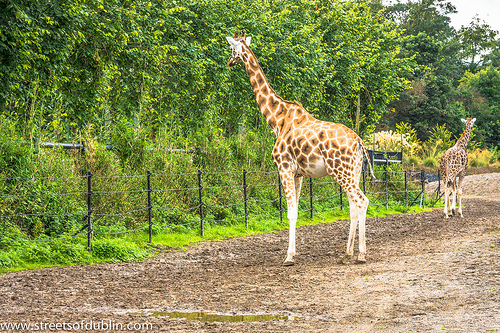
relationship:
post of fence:
[82, 171, 96, 249] [41, 116, 474, 279]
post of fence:
[191, 173, 212, 238] [30, 95, 335, 257]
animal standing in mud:
[225, 31, 376, 266] [1, 171, 498, 331]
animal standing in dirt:
[436, 115, 476, 221] [386, 215, 493, 321]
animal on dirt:
[225, 31, 376, 266] [386, 215, 493, 321]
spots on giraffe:
[291, 140, 355, 180] [184, 21, 371, 267]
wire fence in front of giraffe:
[4, 157, 441, 266] [432, 112, 479, 220]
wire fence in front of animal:
[4, 157, 441, 266] [225, 31, 376, 266]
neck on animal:
[239, 53, 278, 125] [225, 31, 376, 266]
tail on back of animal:
[356, 129, 377, 182] [225, 31, 376, 266]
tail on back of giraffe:
[441, 152, 451, 188] [432, 112, 479, 220]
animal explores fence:
[433, 115, 476, 221] [0, 169, 440, 254]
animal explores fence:
[220, 31, 380, 265] [0, 169, 440, 254]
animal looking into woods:
[225, 31, 376, 266] [20, 13, 209, 138]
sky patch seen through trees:
[448, 26, 498, 69] [437, 28, 497, 120]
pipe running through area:
[27, 140, 402, 166] [0, 0, 490, 327]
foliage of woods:
[18, 16, 193, 153] [0, 0, 498, 270]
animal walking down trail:
[436, 115, 476, 221] [6, 173, 496, 330]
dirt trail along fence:
[0, 200, 492, 331] [0, 136, 271, 260]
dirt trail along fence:
[0, 200, 492, 331] [373, 168, 443, 205]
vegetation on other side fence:
[1, 118, 420, 258] [2, 171, 442, 248]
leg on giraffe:
[355, 197, 375, 258] [222, 38, 390, 263]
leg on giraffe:
[341, 195, 363, 252] [222, 38, 390, 263]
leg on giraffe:
[283, 197, 302, 265] [222, 38, 390, 263]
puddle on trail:
[126, 298, 298, 330] [6, 173, 496, 330]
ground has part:
[395, 272, 451, 308] [401, 259, 438, 303]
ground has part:
[395, 272, 451, 308] [384, 272, 409, 311]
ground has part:
[395, 272, 451, 308] [390, 274, 423, 323]